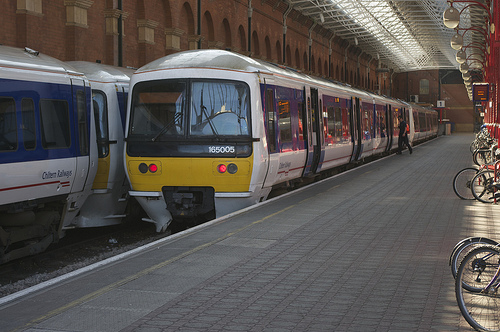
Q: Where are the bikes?
A: On the platform.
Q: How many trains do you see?
A: 2.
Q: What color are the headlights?
A: Red.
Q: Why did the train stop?
A: To pick up passengers.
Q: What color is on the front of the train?
A: Yellow.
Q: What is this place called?
A: A terminal.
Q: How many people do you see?
A: 1.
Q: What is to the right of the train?
A: Bicycles.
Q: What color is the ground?
A: Dark grey.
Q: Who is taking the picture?
A: A photographer.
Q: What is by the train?
A: The platform.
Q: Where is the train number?
A: On the front of the train.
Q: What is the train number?
A: 165005.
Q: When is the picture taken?
A: Daytime.